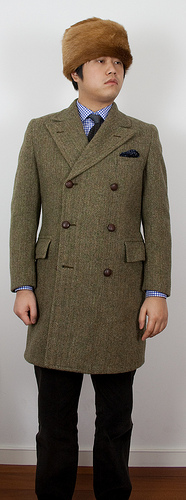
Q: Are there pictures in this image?
A: No, there are no pictures.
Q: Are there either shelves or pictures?
A: No, there are no pictures or shelves.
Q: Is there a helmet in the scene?
A: No, there are no helmets.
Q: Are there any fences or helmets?
A: No, there are no helmets or fences.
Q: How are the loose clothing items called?
A: The clothing items are pants.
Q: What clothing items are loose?
A: The clothing items are pants.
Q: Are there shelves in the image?
A: No, there are no shelves.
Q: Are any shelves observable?
A: No, there are no shelves.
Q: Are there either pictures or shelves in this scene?
A: No, there are no shelves or pictures.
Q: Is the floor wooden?
A: Yes, the floor is wooden.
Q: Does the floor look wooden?
A: Yes, the floor is wooden.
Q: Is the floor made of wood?
A: Yes, the floor is made of wood.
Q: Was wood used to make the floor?
A: Yes, the floor is made of wood.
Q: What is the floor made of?
A: The floor is made of wood.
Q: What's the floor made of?
A: The floor is made of wood.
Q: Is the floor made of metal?
A: No, the floor is made of wood.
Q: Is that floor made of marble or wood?
A: The floor is made of wood.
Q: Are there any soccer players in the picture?
A: No, there are no soccer players.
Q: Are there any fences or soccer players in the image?
A: No, there are no soccer players or fences.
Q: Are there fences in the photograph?
A: No, there are no fences.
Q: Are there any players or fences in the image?
A: No, there are no fences or players.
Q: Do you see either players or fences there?
A: No, there are no fences or players.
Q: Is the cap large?
A: Yes, the cap is large.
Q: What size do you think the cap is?
A: The cap is large.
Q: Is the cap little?
A: No, the cap is large.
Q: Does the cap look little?
A: No, the cap is large.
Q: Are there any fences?
A: No, there are no fences.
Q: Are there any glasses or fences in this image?
A: No, there are no fences or glasses.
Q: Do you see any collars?
A: Yes, there is a collar.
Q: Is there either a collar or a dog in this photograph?
A: Yes, there is a collar.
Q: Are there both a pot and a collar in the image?
A: No, there is a collar but no pots.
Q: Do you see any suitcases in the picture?
A: No, there are no suitcases.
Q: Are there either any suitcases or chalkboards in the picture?
A: No, there are no suitcases or chalkboards.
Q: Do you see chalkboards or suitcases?
A: No, there are no suitcases or chalkboards.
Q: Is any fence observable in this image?
A: No, there are no fences.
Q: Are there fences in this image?
A: No, there are no fences.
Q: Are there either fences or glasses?
A: No, there are no fences or glasses.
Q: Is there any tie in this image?
A: Yes, there is a tie.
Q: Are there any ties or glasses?
A: Yes, there is a tie.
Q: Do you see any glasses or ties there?
A: Yes, there is a tie.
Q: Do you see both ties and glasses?
A: No, there is a tie but no glasses.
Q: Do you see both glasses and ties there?
A: No, there is a tie but no glasses.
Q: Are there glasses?
A: No, there are no glasses.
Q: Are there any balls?
A: No, there are no balls.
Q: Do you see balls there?
A: No, there are no balls.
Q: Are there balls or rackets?
A: No, there are no balls or rackets.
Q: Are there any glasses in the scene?
A: No, there are no glasses.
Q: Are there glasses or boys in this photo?
A: No, there are no glasses or boys.